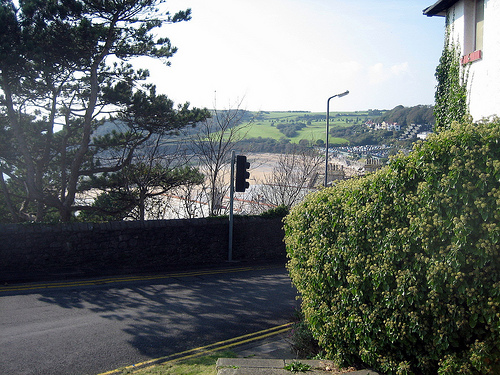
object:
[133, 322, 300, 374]
line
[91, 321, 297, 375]
line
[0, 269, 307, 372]
road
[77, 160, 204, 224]
branch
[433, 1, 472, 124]
vines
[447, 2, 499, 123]
wall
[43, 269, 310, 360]
shadow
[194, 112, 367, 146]
grass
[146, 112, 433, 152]
hill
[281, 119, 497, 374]
bush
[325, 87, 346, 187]
post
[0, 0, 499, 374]
background